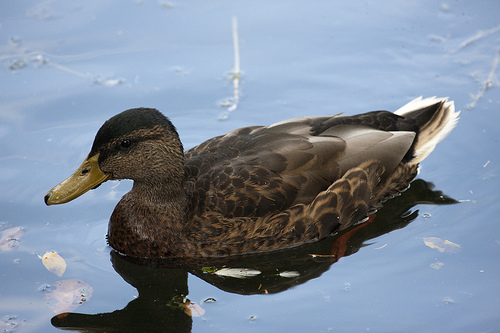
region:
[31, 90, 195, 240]
head of a duck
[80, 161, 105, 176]
nose of a duck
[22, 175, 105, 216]
peck of a duck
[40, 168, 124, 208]
a peck of a duck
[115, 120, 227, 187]
neck of a duck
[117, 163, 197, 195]
a neck of a duck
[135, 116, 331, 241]
body of a duck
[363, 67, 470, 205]
tail of a duck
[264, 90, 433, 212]
feather of a duck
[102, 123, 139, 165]
an eye of a duck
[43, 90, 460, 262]
brown duck in the lake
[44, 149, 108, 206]
large brown peak of duck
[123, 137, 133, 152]
small black right eye of duck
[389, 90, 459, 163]
white feathered tail of duck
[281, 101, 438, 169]
black and gray feathered body of duck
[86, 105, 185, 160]
black line on duck's head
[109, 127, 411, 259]
bron feathers with black dots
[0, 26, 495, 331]
orange leaves on water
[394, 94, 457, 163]
white feathered tail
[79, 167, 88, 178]
little black dot on duck's peak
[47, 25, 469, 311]
A duck in the pond.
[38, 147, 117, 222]
Beak of a duck.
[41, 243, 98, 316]
Leaves floating in the water.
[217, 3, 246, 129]
Branch floating in the water.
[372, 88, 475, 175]
Tail feathers of a duck.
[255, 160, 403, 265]
Wing of a duck.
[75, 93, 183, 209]
Head of the duck.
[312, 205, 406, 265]
Foot of the duck.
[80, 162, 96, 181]
Nostril of the duck.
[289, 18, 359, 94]
Dark blue and calm water.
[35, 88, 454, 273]
brown duck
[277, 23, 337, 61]
ripples in the blue water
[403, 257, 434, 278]
ripples in the blue water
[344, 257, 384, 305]
ripples in the blue water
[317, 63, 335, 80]
ripples in the blue water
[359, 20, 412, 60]
ripples in the blue water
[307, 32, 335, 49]
ripples in the blue water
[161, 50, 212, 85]
ripples in the blue water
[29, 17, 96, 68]
ripples in the blue water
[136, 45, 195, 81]
ripples in the blue water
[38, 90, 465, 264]
DUCK SWIMMING IN WATER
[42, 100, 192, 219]
HEAD OF BROWN DUCK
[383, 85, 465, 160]
TAIL OF BROWN DUCK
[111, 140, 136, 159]
EYE OF BROWN DUCK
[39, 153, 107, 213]
BEAK OF BROWN DUCK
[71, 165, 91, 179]
NOSTRIL OF BROWN DUCK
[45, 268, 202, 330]
REFLECTION OF BROWN DUCK'S HEAD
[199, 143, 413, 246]
PST PF BROWN DUCK'S WING FEATHERS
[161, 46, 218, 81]
CLEAR LIGHT BLUE WATER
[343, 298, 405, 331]
CLEAR LIGHT BLUE WATER